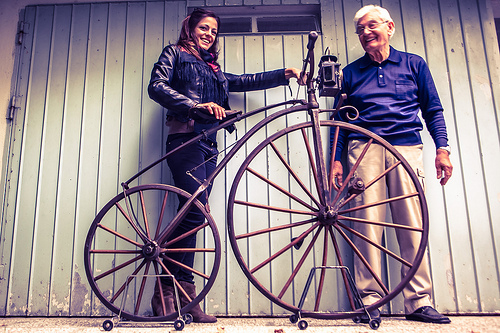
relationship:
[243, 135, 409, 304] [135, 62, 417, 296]
wheel on bike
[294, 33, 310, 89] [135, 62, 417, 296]
handlebars on bike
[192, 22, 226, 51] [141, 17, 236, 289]
face of woman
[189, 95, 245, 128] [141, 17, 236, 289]
hand of woman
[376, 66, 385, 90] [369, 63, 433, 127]
buttons on shirt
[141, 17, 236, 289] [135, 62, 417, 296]
woman holding bike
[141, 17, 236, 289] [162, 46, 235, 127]
woman in leather coat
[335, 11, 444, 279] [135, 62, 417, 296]
man stands by bike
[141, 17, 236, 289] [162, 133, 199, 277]
woman in tight pants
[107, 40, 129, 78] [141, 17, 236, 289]
door behind woman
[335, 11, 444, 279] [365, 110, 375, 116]
man in blue shirt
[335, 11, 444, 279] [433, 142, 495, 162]
man wears watch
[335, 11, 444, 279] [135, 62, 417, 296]
man with bike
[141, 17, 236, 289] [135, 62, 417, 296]
woman with bike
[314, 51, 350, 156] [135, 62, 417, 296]
lantern on bike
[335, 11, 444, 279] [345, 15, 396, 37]
man wears glasses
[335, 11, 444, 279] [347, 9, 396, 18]
man with gray hair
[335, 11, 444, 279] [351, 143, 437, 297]
man in tan pants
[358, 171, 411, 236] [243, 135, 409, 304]
spokes on wheel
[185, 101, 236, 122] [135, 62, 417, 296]
seat on bike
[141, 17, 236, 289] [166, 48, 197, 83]
woman in leather jacket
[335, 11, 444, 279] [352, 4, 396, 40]
man has gray hair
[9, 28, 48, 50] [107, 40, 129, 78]
hinges on door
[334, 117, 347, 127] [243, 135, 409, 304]
edge of wheel